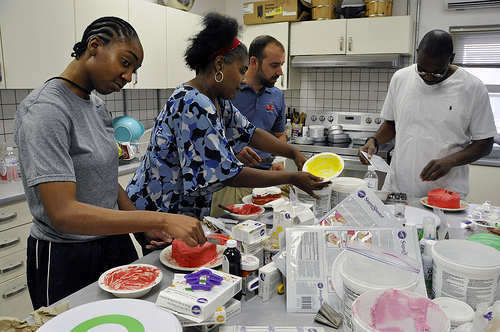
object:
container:
[97, 262, 161, 294]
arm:
[25, 100, 206, 249]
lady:
[14, 16, 150, 283]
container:
[302, 150, 346, 183]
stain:
[308, 157, 341, 176]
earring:
[213, 70, 225, 82]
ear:
[214, 53, 223, 76]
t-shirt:
[18, 80, 131, 239]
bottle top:
[226, 238, 239, 248]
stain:
[109, 269, 155, 286]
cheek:
[92, 52, 117, 81]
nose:
[122, 67, 136, 84]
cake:
[170, 236, 219, 268]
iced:
[200, 229, 229, 247]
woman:
[134, 13, 332, 216]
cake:
[250, 188, 282, 205]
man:
[227, 34, 289, 222]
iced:
[238, 145, 287, 166]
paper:
[357, 147, 393, 178]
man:
[358, 26, 497, 204]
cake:
[427, 188, 463, 210]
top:
[133, 84, 254, 220]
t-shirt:
[370, 65, 499, 195]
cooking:
[133, 159, 494, 327]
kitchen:
[2, 4, 500, 330]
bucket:
[353, 288, 451, 330]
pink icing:
[370, 294, 434, 329]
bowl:
[114, 113, 143, 142]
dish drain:
[115, 132, 155, 162]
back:
[302, 131, 361, 141]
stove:
[297, 133, 390, 156]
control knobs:
[308, 114, 382, 126]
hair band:
[205, 35, 242, 57]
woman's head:
[190, 15, 250, 98]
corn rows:
[89, 17, 131, 40]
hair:
[72, 14, 134, 56]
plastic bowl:
[431, 238, 499, 298]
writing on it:
[436, 270, 498, 299]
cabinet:
[288, 18, 416, 56]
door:
[290, 20, 348, 55]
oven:
[301, 107, 395, 132]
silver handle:
[1, 209, 17, 221]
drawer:
[1, 200, 42, 225]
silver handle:
[2, 238, 19, 249]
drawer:
[1, 227, 38, 253]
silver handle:
[1, 262, 25, 274]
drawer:
[2, 248, 38, 277]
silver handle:
[4, 284, 30, 297]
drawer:
[0, 271, 29, 300]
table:
[45, 194, 498, 330]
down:
[362, 151, 472, 205]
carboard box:
[243, 2, 310, 23]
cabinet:
[242, 22, 290, 90]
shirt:
[228, 79, 286, 160]